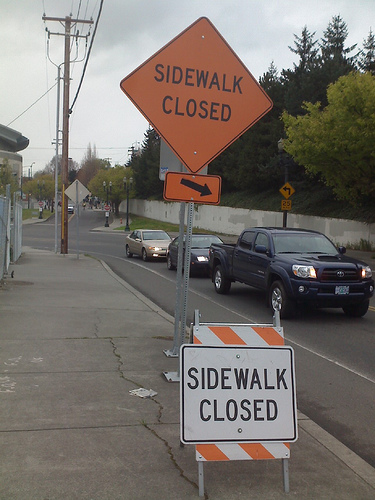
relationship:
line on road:
[66, 243, 373, 391] [0, 206, 372, 465]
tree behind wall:
[277, 58, 374, 213] [115, 192, 371, 256]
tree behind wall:
[281, 2, 355, 202] [115, 192, 371, 256]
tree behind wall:
[273, 16, 318, 191] [115, 192, 371, 256]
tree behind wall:
[246, 63, 280, 184] [115, 192, 371, 256]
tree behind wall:
[138, 119, 162, 193] [115, 192, 371, 256]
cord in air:
[67, 2, 108, 123] [1, 1, 374, 119]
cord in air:
[52, 0, 98, 90] [1, 1, 374, 119]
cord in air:
[61, 2, 92, 59] [1, 1, 374, 119]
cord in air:
[62, 1, 77, 25] [1, 1, 374, 119]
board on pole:
[57, 183, 69, 243] [41, 12, 95, 253]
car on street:
[205, 226, 371, 321] [0, 206, 372, 465]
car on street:
[164, 231, 230, 278] [0, 206, 372, 465]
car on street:
[121, 225, 172, 262] [0, 206, 372, 465]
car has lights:
[205, 226, 371, 321] [289, 262, 321, 285]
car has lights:
[205, 226, 371, 321] [357, 263, 374, 284]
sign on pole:
[162, 169, 228, 207] [165, 200, 210, 355]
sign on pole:
[116, 14, 276, 175] [165, 200, 210, 355]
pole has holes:
[165, 200, 210, 355] [190, 200, 195, 208]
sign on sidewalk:
[176, 305, 306, 499] [0, 248, 373, 499]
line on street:
[66, 243, 373, 391] [0, 206, 372, 465]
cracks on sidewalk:
[86, 298, 107, 347] [0, 248, 373, 499]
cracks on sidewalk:
[99, 337, 133, 377] [0, 248, 373, 499]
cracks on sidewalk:
[114, 372, 170, 423] [0, 248, 373, 499]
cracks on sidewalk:
[140, 419, 215, 498] [0, 248, 373, 499]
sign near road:
[176, 305, 306, 499] [0, 206, 372, 465]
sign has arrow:
[162, 169, 228, 207] [178, 175, 213, 201]